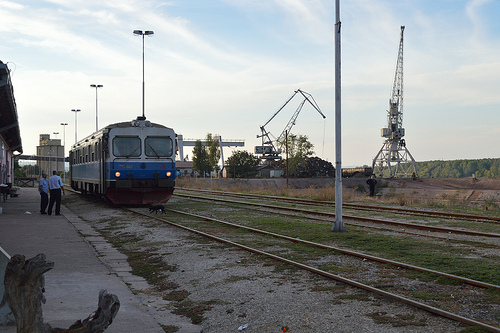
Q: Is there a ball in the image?
A: No, there are no balls.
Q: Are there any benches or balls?
A: No, there are no balls or benches.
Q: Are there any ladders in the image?
A: No, there are no ladders.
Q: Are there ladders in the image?
A: No, there are no ladders.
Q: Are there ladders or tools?
A: No, there are no ladders or tools.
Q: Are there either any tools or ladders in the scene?
A: No, there are no ladders or tools.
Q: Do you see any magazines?
A: No, there are no magazines.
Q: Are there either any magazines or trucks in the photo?
A: No, there are no magazines or trucks.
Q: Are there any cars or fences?
A: No, there are no cars or fences.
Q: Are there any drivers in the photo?
A: No, there are no drivers.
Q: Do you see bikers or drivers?
A: No, there are no drivers or bikers.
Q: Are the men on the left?
A: Yes, the men are on the left of the image.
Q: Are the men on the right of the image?
A: No, the men are on the left of the image.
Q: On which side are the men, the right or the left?
A: The men are on the left of the image.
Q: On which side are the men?
A: The men are on the left of the image.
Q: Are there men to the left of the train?
A: Yes, there are men to the left of the train.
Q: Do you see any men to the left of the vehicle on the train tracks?
A: Yes, there are men to the left of the train.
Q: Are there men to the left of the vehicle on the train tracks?
A: Yes, there are men to the left of the train.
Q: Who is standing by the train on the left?
A: The men are standing by the train.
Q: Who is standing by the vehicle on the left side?
A: The men are standing by the train.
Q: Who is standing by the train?
A: The men are standing by the train.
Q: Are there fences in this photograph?
A: No, there are no fences.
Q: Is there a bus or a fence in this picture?
A: No, there are no fences or buses.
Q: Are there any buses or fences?
A: No, there are no fences or buses.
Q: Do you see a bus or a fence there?
A: No, there are no fences or buses.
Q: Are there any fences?
A: No, there are no fences.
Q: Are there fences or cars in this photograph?
A: No, there are no fences or cars.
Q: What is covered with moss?
A: The tracks are covered with moss.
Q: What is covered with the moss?
A: The tracks are covered with moss.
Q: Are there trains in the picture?
A: Yes, there is a train.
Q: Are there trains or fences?
A: Yes, there is a train.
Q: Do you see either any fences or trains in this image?
A: Yes, there is a train.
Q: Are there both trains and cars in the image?
A: No, there is a train but no cars.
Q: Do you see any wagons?
A: No, there are no wagons.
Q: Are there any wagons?
A: No, there are no wagons.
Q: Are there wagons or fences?
A: No, there are no wagons or fences.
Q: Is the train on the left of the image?
A: Yes, the train is on the left of the image.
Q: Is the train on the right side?
A: No, the train is on the left of the image.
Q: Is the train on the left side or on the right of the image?
A: The train is on the left of the image.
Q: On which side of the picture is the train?
A: The train is on the left of the image.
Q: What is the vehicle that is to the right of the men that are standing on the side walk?
A: The vehicle is a train.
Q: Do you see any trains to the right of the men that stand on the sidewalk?
A: Yes, there is a train to the right of the men.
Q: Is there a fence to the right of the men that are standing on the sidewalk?
A: No, there is a train to the right of the men.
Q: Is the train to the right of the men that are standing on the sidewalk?
A: Yes, the train is to the right of the men.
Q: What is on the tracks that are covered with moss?
A: The train is on the tracks.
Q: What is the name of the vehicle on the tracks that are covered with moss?
A: The vehicle is a train.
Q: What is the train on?
A: The train is on the railroad tracks.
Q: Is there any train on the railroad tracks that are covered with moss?
A: Yes, there is a train on the tracks.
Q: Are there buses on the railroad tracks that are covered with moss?
A: No, there is a train on the railroad tracks.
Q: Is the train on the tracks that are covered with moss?
A: Yes, the train is on the railroad tracks.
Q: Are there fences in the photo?
A: No, there are no fences.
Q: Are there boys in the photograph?
A: No, there are no boys.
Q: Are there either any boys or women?
A: No, there are no boys or women.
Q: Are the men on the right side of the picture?
A: No, the men are on the left of the image.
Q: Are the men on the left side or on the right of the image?
A: The men are on the left of the image.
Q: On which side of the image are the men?
A: The men are on the left of the image.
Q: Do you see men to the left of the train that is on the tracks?
A: Yes, there are men to the left of the train.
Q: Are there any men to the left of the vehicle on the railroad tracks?
A: Yes, there are men to the left of the train.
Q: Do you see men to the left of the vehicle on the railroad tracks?
A: Yes, there are men to the left of the train.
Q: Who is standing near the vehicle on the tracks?
A: The men are standing near the train.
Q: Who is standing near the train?
A: The men are standing near the train.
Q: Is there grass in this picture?
A: Yes, there is grass.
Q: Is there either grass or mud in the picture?
A: Yes, there is grass.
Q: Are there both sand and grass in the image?
A: No, there is grass but no sand.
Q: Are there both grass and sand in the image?
A: No, there is grass but no sand.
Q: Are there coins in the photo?
A: No, there are no coins.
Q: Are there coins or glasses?
A: No, there are no coins or glasses.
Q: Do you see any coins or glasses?
A: No, there are no coins or glasses.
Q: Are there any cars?
A: No, there are no cars.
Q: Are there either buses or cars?
A: No, there are no cars or buses.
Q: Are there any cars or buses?
A: No, there are no cars or buses.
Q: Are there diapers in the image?
A: No, there are no diapers.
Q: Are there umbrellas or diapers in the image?
A: No, there are no diapers or umbrellas.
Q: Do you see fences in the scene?
A: No, there are no fences.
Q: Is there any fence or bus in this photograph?
A: No, there are no fences or buses.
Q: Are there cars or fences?
A: No, there are no cars or fences.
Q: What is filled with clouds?
A: The sky is filled with clouds.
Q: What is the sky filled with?
A: The sky is filled with clouds.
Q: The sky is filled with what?
A: The sky is filled with clouds.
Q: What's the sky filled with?
A: The sky is filled with clouds.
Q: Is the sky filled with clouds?
A: Yes, the sky is filled with clouds.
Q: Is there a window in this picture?
A: Yes, there are windows.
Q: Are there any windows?
A: Yes, there are windows.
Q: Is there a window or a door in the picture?
A: Yes, there are windows.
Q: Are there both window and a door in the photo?
A: No, there are windows but no doors.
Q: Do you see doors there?
A: No, there are no doors.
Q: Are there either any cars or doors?
A: No, there are no doors or cars.